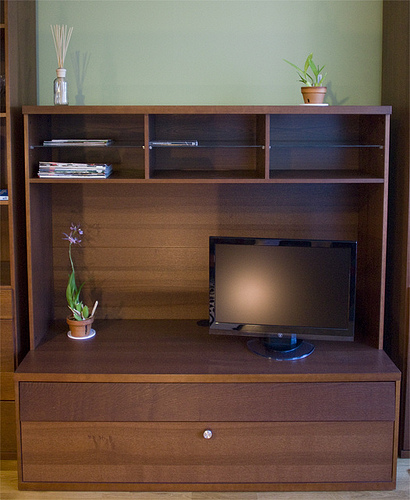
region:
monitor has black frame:
[203, 240, 364, 355]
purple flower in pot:
[60, 232, 105, 332]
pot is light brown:
[69, 305, 107, 353]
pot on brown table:
[48, 297, 116, 363]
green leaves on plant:
[69, 272, 90, 319]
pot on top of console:
[280, 55, 330, 103]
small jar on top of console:
[48, 32, 76, 102]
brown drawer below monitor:
[40, 415, 386, 477]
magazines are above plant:
[30, 150, 112, 181]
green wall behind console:
[164, 32, 261, 98]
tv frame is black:
[204, 229, 362, 366]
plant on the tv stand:
[57, 219, 107, 340]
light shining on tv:
[212, 262, 301, 330]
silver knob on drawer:
[198, 422, 217, 445]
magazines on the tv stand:
[33, 134, 113, 180]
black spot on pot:
[306, 96, 312, 107]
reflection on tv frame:
[247, 235, 336, 249]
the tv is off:
[201, 228, 362, 364]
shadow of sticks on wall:
[70, 48, 92, 105]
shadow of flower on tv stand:
[77, 224, 129, 320]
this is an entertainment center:
[22, 49, 375, 441]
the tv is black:
[185, 192, 368, 393]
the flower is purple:
[48, 213, 137, 354]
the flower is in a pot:
[29, 192, 133, 332]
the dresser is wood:
[158, 396, 283, 490]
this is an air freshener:
[34, 11, 147, 128]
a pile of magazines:
[23, 119, 122, 197]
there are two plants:
[21, 11, 379, 398]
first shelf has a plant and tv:
[41, 207, 372, 382]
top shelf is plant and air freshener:
[35, 16, 358, 118]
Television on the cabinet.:
[188, 223, 365, 365]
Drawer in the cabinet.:
[13, 414, 391, 481]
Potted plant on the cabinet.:
[50, 212, 103, 338]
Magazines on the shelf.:
[36, 157, 115, 181]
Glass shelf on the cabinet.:
[271, 134, 383, 154]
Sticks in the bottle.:
[41, 20, 76, 105]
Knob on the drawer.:
[199, 423, 215, 441]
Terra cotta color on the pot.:
[298, 83, 329, 102]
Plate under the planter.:
[66, 327, 98, 341]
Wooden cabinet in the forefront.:
[13, 86, 402, 493]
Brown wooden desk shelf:
[18, 101, 398, 489]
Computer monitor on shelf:
[203, 231, 363, 359]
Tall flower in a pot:
[63, 222, 96, 339]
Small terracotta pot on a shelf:
[67, 316, 94, 335]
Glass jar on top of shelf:
[53, 67, 71, 108]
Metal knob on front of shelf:
[197, 427, 211, 438]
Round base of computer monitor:
[251, 335, 313, 360]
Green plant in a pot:
[287, 57, 326, 105]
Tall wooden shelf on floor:
[0, 5, 36, 461]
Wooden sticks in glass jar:
[49, 21, 72, 64]